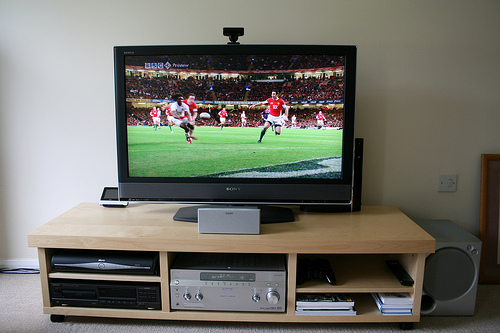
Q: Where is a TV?
A: On a table.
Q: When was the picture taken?
A: In a room.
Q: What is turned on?
A: TV.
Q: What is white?
A: Wall.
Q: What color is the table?
A: Light brown.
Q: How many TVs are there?
A: One.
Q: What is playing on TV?
A: A soccer game.